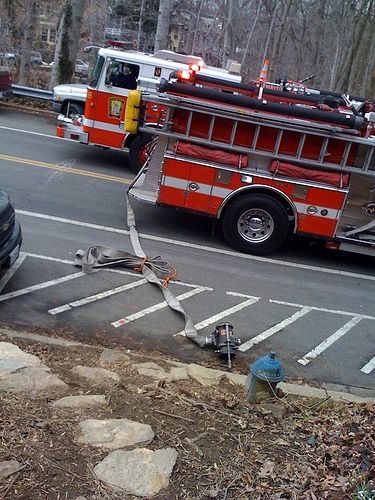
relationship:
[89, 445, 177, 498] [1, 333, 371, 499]
rock in dirt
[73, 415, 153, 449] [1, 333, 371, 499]
rock in dirt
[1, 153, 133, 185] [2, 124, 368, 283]
line on road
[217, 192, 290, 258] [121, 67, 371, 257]
tire on engine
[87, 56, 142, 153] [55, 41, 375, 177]
door of engine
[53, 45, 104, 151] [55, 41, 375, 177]
front of engine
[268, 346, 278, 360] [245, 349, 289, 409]
bolt on hydrant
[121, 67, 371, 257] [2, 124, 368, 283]
engine on road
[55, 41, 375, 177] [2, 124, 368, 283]
engine on road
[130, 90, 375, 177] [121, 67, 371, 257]
ladder of engine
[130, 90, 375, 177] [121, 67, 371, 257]
ladder on engine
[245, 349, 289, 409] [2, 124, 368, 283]
hydrant on side of road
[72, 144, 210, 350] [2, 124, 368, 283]
hose on road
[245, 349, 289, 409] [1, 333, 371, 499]
hydrant on dirt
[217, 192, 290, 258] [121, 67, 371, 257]
tire of engine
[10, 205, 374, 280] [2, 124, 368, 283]
line on road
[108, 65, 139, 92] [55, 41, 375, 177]
man in engine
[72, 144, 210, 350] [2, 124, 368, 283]
hose in road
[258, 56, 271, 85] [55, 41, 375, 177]
cone on engine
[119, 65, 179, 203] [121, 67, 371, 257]
end of engine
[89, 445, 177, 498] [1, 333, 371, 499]
rock on dirt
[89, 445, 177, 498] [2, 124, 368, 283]
rock by road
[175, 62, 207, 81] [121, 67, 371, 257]
lights on engine